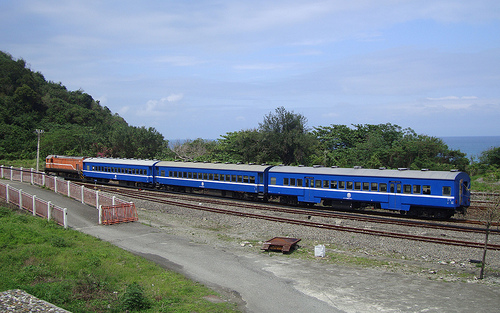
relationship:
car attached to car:
[44, 154, 86, 181] [83, 156, 156, 187]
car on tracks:
[44, 154, 86, 181] [70, 177, 499, 250]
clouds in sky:
[402, 89, 490, 119] [1, 1, 499, 135]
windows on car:
[282, 173, 451, 198] [44, 154, 86, 181]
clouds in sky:
[122, 92, 194, 124] [1, 1, 499, 135]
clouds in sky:
[37, 7, 312, 46] [1, 1, 499, 135]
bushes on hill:
[49, 100, 93, 127] [0, 53, 168, 158]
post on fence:
[63, 206, 70, 229] [0, 166, 138, 228]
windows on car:
[169, 169, 257, 184] [44, 154, 86, 181]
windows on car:
[91, 165, 149, 176] [44, 154, 86, 181]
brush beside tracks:
[213, 106, 469, 167] [70, 177, 499, 250]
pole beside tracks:
[33, 126, 45, 171] [70, 177, 499, 250]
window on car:
[440, 182, 451, 195] [44, 154, 86, 181]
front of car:
[453, 171, 469, 212] [44, 154, 86, 181]